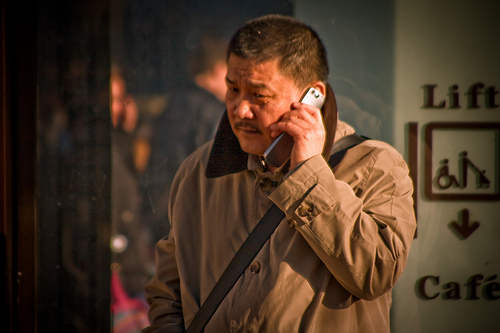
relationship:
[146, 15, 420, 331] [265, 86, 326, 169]
man on phone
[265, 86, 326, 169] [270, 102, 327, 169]
phone in hand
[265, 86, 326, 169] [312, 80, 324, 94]
phone to ear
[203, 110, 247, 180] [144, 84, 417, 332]
collar of coat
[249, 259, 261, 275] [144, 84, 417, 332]
button on coat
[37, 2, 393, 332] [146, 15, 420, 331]
window behind man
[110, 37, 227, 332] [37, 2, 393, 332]
people behind window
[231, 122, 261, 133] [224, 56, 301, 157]
mustache on face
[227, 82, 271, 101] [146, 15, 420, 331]
eyes of man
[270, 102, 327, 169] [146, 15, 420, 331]
hand of man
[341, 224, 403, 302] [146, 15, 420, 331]
elbow of man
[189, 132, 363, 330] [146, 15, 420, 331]
strap on man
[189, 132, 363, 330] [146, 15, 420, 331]
strap around man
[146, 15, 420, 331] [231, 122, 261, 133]
man has a mustache